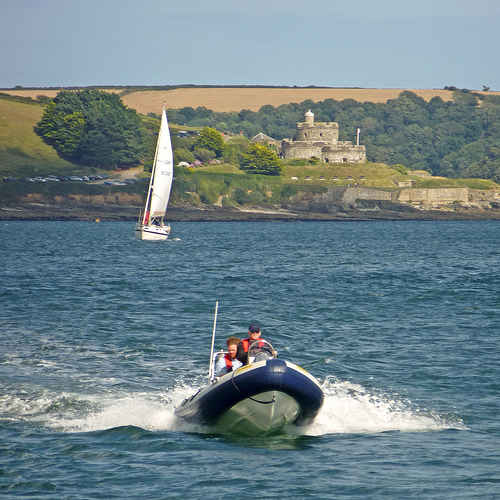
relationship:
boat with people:
[113, 263, 370, 452] [202, 308, 303, 365]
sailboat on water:
[81, 87, 267, 286] [289, 227, 462, 317]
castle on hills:
[258, 95, 424, 205] [4, 100, 59, 186]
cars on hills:
[29, 159, 120, 191] [4, 100, 59, 186]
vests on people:
[204, 347, 265, 364] [202, 308, 303, 365]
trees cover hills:
[279, 95, 493, 171] [4, 100, 59, 186]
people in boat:
[202, 308, 303, 365] [113, 263, 370, 452]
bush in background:
[65, 104, 142, 170] [17, 79, 492, 225]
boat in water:
[113, 263, 370, 452] [289, 227, 462, 317]